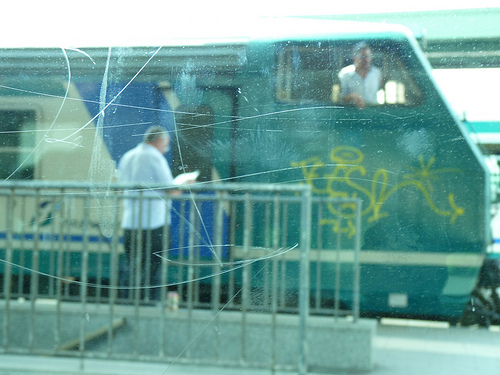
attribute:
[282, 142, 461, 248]
graffitti on train — yellow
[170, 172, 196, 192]
newspaper — white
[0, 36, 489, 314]
train — light , green, caligraphed, yellow, long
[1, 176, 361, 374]
metal fences — tall, pole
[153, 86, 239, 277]
train door — blue, green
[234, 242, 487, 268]
white strip — long, painted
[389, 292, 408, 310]
white square — small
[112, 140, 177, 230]
shirt — white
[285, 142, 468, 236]
graffiti — large, scribbled, yellow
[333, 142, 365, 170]
circle — yellow, scribbled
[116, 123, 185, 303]
man — waiting